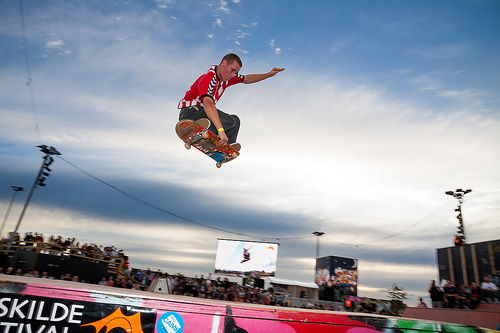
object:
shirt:
[176, 65, 245, 112]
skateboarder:
[173, 52, 285, 169]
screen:
[211, 237, 280, 277]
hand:
[213, 135, 229, 148]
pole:
[0, 190, 16, 237]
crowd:
[415, 271, 500, 311]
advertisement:
[153, 309, 186, 333]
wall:
[0, 270, 499, 333]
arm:
[236, 72, 270, 84]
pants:
[176, 105, 239, 145]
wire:
[16, 0, 46, 146]